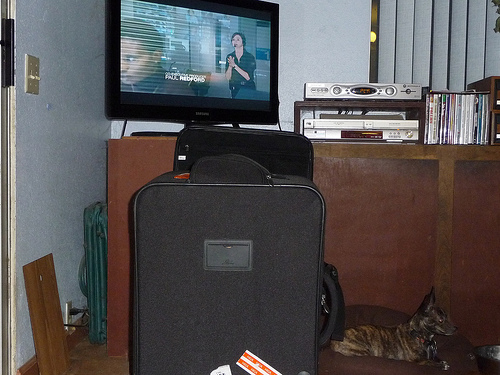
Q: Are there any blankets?
A: No, there are no blankets.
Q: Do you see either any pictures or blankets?
A: No, there are no blankets or pictures.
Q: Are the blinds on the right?
A: Yes, the blinds are on the right of the image.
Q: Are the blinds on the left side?
A: No, the blinds are on the right of the image.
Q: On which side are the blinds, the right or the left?
A: The blinds are on the right of the image.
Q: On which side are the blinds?
A: The blinds are on the right of the image.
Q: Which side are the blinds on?
A: The blinds are on the right of the image.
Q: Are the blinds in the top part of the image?
A: Yes, the blinds are in the top of the image.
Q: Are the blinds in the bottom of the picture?
A: No, the blinds are in the top of the image.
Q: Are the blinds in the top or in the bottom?
A: The blinds are in the top of the image.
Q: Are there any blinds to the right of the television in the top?
A: Yes, there are blinds to the right of the television.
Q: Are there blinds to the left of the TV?
A: No, the blinds are to the right of the TV.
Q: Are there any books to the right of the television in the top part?
A: No, there are blinds to the right of the television.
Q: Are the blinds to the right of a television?
A: Yes, the blinds are to the right of a television.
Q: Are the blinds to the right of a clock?
A: No, the blinds are to the right of a television.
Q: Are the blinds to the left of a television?
A: No, the blinds are to the right of a television.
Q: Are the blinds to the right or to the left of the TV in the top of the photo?
A: The blinds are to the right of the TV.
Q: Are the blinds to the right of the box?
A: Yes, the blinds are to the right of the box.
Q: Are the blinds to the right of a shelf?
A: No, the blinds are to the right of the box.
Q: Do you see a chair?
A: No, there are no chairs.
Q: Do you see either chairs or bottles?
A: No, there are no chairs or bottles.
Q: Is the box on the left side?
A: No, the box is on the right of the image.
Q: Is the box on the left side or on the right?
A: The box is on the right of the image.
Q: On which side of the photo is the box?
A: The box is on the right of the image.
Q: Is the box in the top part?
A: Yes, the box is in the top of the image.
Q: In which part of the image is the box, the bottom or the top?
A: The box is in the top of the image.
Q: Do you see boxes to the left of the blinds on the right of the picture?
A: Yes, there is a box to the left of the blinds.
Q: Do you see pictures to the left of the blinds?
A: No, there is a box to the left of the blinds.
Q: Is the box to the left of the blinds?
A: Yes, the box is to the left of the blinds.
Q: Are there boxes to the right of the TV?
A: Yes, there is a box to the right of the TV.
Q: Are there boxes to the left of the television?
A: No, the box is to the right of the television.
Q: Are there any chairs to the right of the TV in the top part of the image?
A: No, there is a box to the right of the television.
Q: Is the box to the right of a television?
A: Yes, the box is to the right of a television.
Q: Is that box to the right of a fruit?
A: No, the box is to the right of a television.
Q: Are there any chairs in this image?
A: No, there are no chairs.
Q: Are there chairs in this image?
A: No, there are no chairs.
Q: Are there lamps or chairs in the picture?
A: No, there are no chairs or lamps.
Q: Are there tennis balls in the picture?
A: No, there are no tennis balls.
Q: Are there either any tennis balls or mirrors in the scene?
A: No, there are no tennis balls or mirrors.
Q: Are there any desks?
A: Yes, there is a desk.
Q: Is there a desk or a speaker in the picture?
A: Yes, there is a desk.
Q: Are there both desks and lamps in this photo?
A: No, there is a desk but no lamps.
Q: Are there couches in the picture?
A: No, there are no couches.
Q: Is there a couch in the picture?
A: No, there are no couches.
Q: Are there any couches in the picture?
A: No, there are no couches.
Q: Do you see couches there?
A: No, there are no couches.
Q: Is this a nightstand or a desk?
A: This is a desk.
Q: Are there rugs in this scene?
A: No, there are no rugs.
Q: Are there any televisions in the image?
A: Yes, there is a television.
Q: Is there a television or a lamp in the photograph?
A: Yes, there is a television.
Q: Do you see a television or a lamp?
A: Yes, there is a television.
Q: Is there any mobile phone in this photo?
A: No, there are no cell phones.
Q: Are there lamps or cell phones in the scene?
A: No, there are no cell phones or lamps.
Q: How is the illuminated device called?
A: The device is a television.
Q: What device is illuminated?
A: The device is a television.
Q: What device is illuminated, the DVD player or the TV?
A: The TV is illuminated.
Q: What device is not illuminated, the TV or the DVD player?
A: The DVD player is not illuminated.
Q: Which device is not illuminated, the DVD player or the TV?
A: The DVD player is not illuminated.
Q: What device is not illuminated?
A: The device is a DVD player.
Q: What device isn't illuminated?
A: The device is a DVD player.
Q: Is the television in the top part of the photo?
A: Yes, the television is in the top of the image.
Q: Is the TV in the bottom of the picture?
A: No, the TV is in the top of the image.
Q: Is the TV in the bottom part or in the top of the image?
A: The TV is in the top of the image.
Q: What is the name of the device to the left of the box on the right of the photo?
A: The device is a television.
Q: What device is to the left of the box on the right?
A: The device is a television.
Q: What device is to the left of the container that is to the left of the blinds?
A: The device is a television.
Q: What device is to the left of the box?
A: The device is a television.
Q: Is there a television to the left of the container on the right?
A: Yes, there is a television to the left of the box.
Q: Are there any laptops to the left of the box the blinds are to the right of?
A: No, there is a television to the left of the box.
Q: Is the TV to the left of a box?
A: Yes, the TV is to the left of a box.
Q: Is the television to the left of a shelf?
A: No, the television is to the left of a box.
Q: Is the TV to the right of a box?
A: No, the TV is to the left of a box.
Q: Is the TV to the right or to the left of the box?
A: The TV is to the left of the box.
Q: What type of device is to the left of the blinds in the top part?
A: The device is a television.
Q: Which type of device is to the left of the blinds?
A: The device is a television.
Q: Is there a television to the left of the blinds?
A: Yes, there is a television to the left of the blinds.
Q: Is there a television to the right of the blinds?
A: No, the television is to the left of the blinds.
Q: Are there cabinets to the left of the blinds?
A: No, there is a television to the left of the blinds.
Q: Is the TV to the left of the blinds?
A: Yes, the TV is to the left of the blinds.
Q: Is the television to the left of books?
A: No, the television is to the left of the blinds.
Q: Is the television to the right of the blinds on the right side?
A: No, the television is to the left of the blinds.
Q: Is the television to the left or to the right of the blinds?
A: The television is to the left of the blinds.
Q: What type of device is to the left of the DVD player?
A: The device is a television.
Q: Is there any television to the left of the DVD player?
A: Yes, there is a television to the left of the DVD player.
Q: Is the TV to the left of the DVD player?
A: Yes, the TV is to the left of the DVD player.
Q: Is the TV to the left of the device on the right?
A: Yes, the TV is to the left of the DVD player.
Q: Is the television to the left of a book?
A: No, the television is to the left of the DVD player.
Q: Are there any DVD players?
A: Yes, there is a DVD player.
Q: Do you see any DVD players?
A: Yes, there is a DVD player.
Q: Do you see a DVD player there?
A: Yes, there is a DVD player.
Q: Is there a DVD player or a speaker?
A: Yes, there is a DVD player.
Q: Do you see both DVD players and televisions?
A: Yes, there are both a DVD player and a television.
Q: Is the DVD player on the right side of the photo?
A: Yes, the DVD player is on the right of the image.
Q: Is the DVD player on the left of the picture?
A: No, the DVD player is on the right of the image.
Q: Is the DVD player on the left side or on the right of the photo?
A: The DVD player is on the right of the image.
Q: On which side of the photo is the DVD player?
A: The DVD player is on the right of the image.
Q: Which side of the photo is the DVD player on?
A: The DVD player is on the right of the image.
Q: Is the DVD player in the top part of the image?
A: Yes, the DVD player is in the top of the image.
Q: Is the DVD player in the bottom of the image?
A: No, the DVD player is in the top of the image.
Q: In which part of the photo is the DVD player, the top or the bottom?
A: The DVD player is in the top of the image.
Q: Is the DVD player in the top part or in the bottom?
A: The DVD player is in the top of the image.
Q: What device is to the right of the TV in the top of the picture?
A: The device is a DVD player.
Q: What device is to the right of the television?
A: The device is a DVD player.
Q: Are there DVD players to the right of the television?
A: Yes, there is a DVD player to the right of the television.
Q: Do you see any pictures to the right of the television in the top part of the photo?
A: No, there is a DVD player to the right of the TV.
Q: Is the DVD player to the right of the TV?
A: Yes, the DVD player is to the right of the TV.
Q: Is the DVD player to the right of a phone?
A: No, the DVD player is to the right of the TV.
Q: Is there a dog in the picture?
A: Yes, there is a dog.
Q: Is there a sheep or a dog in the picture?
A: Yes, there is a dog.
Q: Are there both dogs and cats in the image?
A: No, there is a dog but no cats.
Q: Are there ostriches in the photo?
A: No, there are no ostriches.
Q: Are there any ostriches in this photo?
A: No, there are no ostriches.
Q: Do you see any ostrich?
A: No, there are no ostriches.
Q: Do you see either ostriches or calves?
A: No, there are no ostriches or calves.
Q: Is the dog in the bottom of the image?
A: Yes, the dog is in the bottom of the image.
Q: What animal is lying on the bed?
A: The dog is lying on the bed.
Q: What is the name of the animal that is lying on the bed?
A: The animal is a dog.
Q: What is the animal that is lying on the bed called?
A: The animal is a dog.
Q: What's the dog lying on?
A: The dog is lying on the bed.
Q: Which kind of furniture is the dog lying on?
A: The dog is lying on the bed.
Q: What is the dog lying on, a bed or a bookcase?
A: The dog is lying on a bed.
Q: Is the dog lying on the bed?
A: Yes, the dog is lying on the bed.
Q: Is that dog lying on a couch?
A: No, the dog is lying on the bed.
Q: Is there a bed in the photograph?
A: Yes, there is a bed.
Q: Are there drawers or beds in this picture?
A: Yes, there is a bed.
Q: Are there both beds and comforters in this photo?
A: No, there is a bed but no comforters.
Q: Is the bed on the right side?
A: Yes, the bed is on the right of the image.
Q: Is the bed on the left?
A: No, the bed is on the right of the image.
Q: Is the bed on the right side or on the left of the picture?
A: The bed is on the right of the image.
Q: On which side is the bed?
A: The bed is on the right of the image.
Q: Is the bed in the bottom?
A: Yes, the bed is in the bottom of the image.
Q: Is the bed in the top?
A: No, the bed is in the bottom of the image.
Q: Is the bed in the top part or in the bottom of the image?
A: The bed is in the bottom of the image.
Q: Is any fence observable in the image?
A: No, there are no fences.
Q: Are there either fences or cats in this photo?
A: No, there are no fences or cats.